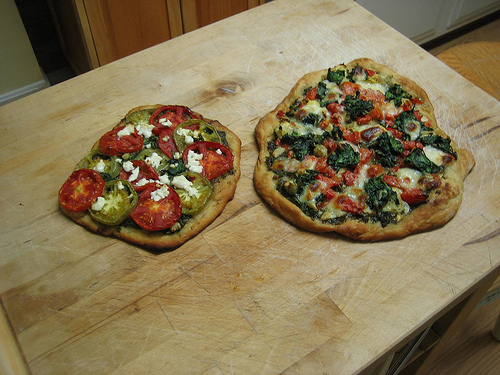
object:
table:
[0, 0, 500, 373]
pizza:
[58, 103, 242, 255]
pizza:
[251, 56, 476, 245]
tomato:
[173, 120, 222, 158]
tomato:
[170, 171, 214, 215]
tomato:
[88, 178, 139, 225]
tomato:
[181, 141, 233, 181]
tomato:
[129, 184, 183, 231]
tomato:
[58, 169, 106, 212]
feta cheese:
[186, 150, 204, 174]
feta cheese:
[144, 152, 162, 168]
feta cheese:
[92, 197, 106, 211]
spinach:
[368, 132, 405, 168]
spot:
[198, 79, 246, 101]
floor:
[413, 20, 499, 374]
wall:
[0, 0, 51, 109]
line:
[233, 296, 261, 337]